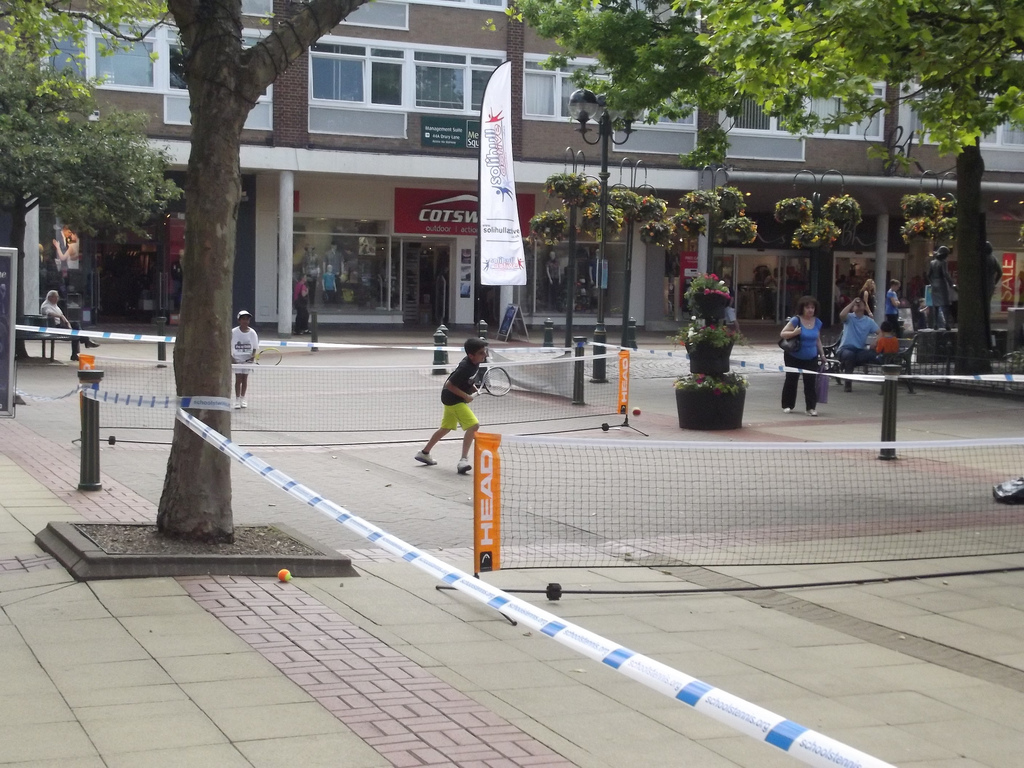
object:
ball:
[277, 568, 291, 582]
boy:
[413, 336, 492, 475]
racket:
[463, 366, 512, 403]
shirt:
[781, 315, 824, 360]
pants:
[781, 354, 817, 411]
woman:
[777, 297, 831, 418]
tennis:
[27, 302, 1023, 708]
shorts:
[440, 401, 479, 432]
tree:
[154, 0, 375, 544]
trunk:
[154, 97, 242, 551]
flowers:
[526, 209, 567, 247]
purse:
[777, 315, 804, 353]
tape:
[5, 389, 912, 768]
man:
[41, 289, 101, 360]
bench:
[16, 315, 85, 363]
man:
[833, 297, 882, 392]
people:
[545, 250, 562, 310]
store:
[291, 173, 642, 334]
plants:
[671, 272, 750, 432]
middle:
[581, 338, 885, 457]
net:
[77, 347, 630, 433]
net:
[473, 431, 1021, 573]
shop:
[0, 161, 255, 334]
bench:
[814, 330, 920, 397]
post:
[589, 111, 611, 385]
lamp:
[567, 86, 600, 123]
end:
[473, 432, 501, 574]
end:
[619, 351, 628, 412]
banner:
[479, 58, 526, 285]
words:
[488, 177, 501, 185]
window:
[310, 52, 367, 103]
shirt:
[837, 312, 883, 352]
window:
[275, 213, 390, 317]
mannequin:
[321, 263, 338, 303]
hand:
[462, 393, 475, 404]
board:
[495, 302, 530, 342]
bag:
[814, 363, 828, 404]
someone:
[230, 310, 260, 409]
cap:
[236, 310, 253, 321]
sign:
[394, 187, 536, 238]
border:
[77, 354, 94, 430]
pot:
[676, 384, 747, 432]